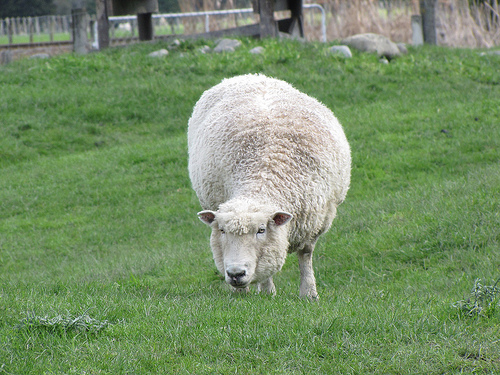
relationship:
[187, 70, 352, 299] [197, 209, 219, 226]
sheep has ear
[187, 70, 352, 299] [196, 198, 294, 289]
sheep has head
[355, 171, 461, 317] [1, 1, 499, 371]
grass in pasture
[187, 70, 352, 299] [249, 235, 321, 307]
sheep has front legs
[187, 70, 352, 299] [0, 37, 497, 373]
sheep eating grass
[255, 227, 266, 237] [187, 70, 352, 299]
eye on sheep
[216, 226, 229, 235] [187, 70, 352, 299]
eye on sheep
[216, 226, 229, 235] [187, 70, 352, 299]
eye of sheep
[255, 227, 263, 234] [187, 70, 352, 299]
eye of sheep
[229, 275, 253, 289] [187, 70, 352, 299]
sheep mouth on sheep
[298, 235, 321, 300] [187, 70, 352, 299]
front legs on sheep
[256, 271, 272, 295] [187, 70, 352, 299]
leg on sheep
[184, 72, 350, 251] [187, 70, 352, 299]
round body of sheep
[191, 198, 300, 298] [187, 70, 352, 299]
head of sheep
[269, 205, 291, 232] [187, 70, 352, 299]
ear of sheep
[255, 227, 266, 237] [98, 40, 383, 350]
eye of sheep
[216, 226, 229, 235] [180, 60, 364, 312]
eye of sheep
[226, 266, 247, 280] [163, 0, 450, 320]
nose of sheep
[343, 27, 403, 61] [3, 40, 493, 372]
rock in field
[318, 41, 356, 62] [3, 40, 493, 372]
rock in field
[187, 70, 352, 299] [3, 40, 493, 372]
sheep in field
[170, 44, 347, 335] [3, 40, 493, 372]
sheep in field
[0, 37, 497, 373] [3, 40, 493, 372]
grass in field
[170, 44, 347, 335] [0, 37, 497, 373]
sheep eating grass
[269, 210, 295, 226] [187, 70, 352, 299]
ear on sheep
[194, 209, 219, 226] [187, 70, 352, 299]
ear on sheep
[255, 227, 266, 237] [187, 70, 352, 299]
eye of sheep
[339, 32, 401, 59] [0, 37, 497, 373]
boulder in grass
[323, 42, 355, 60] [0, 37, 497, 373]
boulder in grass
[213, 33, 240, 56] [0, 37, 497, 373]
boulder in grass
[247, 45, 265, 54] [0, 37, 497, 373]
boulder in grass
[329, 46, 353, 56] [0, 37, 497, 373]
boulder in grass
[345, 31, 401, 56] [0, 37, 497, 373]
boulder in grass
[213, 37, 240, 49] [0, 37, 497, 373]
boulder in grass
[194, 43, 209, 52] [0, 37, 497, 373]
boulder in grass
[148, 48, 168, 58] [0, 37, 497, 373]
boulder in grass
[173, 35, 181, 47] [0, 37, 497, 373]
boulder in grass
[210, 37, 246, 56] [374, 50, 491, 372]
boulder in grass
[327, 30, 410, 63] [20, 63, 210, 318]
rocks in field